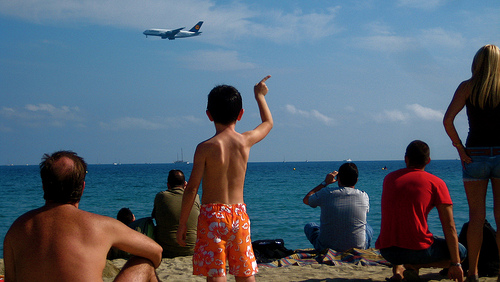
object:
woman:
[440, 42, 500, 282]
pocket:
[459, 156, 481, 176]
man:
[369, 134, 469, 280]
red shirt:
[376, 165, 452, 248]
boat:
[170, 148, 195, 168]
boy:
[180, 76, 272, 279]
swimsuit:
[184, 200, 263, 276]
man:
[302, 158, 372, 255]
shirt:
[308, 185, 368, 250]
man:
[6, 150, 171, 280]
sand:
[100, 245, 497, 280]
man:
[148, 162, 201, 254]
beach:
[118, 177, 351, 276]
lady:
[439, 43, 499, 279]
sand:
[354, 262, 381, 280]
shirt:
[369, 165, 456, 254]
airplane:
[132, 19, 209, 41]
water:
[0, 153, 499, 257]